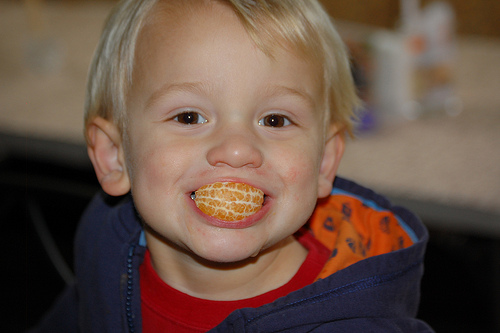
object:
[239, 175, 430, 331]
hood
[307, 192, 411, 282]
inseam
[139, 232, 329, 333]
red shirt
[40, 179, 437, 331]
sweatshirt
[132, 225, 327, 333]
top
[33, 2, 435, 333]
boy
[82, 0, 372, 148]
hair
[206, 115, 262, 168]
nose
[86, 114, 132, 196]
left ear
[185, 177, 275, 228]
boy's mouth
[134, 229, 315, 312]
shirt neck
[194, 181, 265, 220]
fruit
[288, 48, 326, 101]
ground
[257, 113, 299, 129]
eye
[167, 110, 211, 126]
eye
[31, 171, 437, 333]
blue hoodie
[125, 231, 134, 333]
zipper